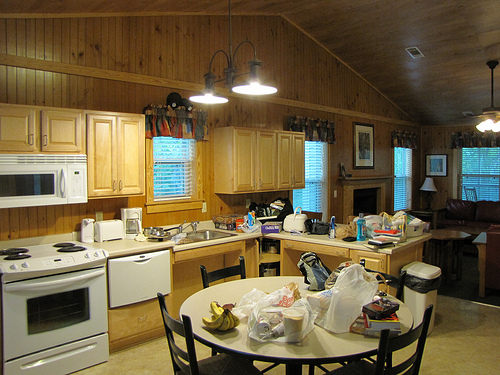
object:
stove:
[54, 245, 87, 254]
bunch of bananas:
[202, 299, 242, 332]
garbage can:
[400, 257, 444, 338]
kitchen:
[1, 0, 499, 373]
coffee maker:
[119, 205, 147, 242]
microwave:
[0, 151, 91, 211]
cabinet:
[1, 103, 37, 153]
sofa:
[430, 197, 500, 246]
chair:
[150, 293, 263, 375]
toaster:
[95, 218, 127, 244]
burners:
[3, 251, 33, 261]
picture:
[352, 120, 379, 171]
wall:
[331, 119, 401, 221]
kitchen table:
[177, 272, 443, 374]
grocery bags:
[307, 260, 380, 340]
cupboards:
[212, 123, 256, 197]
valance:
[143, 103, 210, 142]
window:
[145, 109, 204, 202]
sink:
[178, 229, 237, 245]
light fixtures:
[178, 0, 282, 109]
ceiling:
[3, 0, 496, 126]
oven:
[0, 267, 113, 375]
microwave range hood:
[0, 154, 87, 165]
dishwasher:
[106, 249, 174, 312]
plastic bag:
[232, 279, 319, 346]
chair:
[327, 303, 435, 372]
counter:
[93, 231, 170, 257]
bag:
[403, 273, 441, 295]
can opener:
[80, 218, 96, 244]